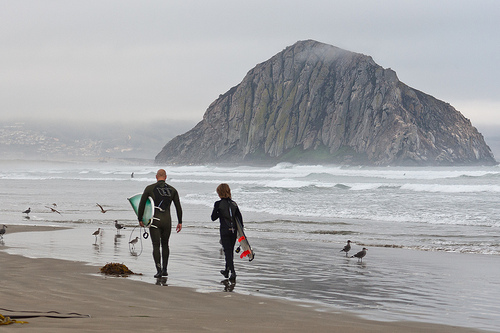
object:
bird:
[339, 240, 351, 255]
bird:
[350, 248, 368, 262]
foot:
[220, 270, 228, 278]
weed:
[100, 263, 133, 275]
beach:
[0, 183, 499, 332]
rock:
[275, 86, 296, 131]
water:
[0, 164, 499, 223]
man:
[138, 169, 184, 277]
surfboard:
[231, 208, 254, 261]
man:
[211, 183, 244, 279]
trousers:
[221, 234, 238, 272]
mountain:
[160, 39, 494, 168]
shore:
[0, 226, 498, 329]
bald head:
[155, 169, 166, 181]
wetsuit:
[211, 199, 243, 268]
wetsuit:
[138, 180, 183, 267]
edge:
[312, 39, 403, 84]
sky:
[2, 0, 495, 126]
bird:
[92, 228, 101, 236]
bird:
[96, 203, 113, 214]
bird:
[22, 207, 30, 215]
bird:
[0, 224, 8, 234]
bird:
[129, 237, 141, 250]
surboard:
[126, 193, 154, 227]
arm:
[137, 185, 151, 221]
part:
[240, 239, 255, 261]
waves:
[264, 181, 312, 188]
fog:
[0, 0, 499, 119]